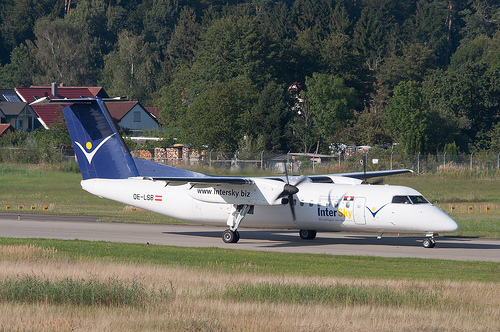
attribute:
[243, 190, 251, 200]
letter — blue 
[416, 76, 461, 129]
leaves — green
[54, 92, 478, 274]
plane — white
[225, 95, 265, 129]
leaves — green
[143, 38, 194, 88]
leaves — green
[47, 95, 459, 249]
airplane — propeller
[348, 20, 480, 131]
leaves — green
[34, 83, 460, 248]
airplane — small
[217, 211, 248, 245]
landing gear — rear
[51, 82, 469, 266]
plane — white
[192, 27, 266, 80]
leaves — green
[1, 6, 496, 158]
trees — brown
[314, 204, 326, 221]
letter — blue 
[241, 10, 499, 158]
trees — brown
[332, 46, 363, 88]
leaves — green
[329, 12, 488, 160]
trees — brown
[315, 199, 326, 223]
letter — blue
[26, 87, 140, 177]
tail — blue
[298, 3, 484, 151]
trees — brown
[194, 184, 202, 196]
letter — blue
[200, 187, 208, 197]
letter — blue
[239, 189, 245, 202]
letter — blue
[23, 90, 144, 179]
tail — blue, painted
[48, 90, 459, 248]
plane — white, blue